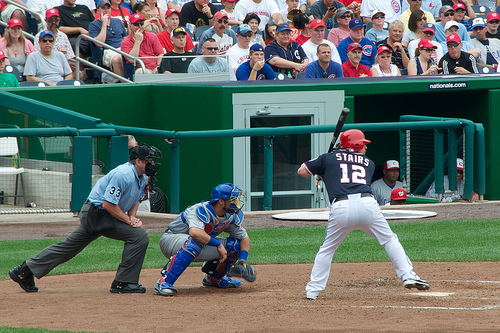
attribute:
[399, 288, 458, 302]
plate — home, white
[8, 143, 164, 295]
umpire — at game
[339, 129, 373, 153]
helmet — red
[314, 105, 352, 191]
bat — black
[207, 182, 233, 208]
helmet — blue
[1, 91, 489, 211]
railing — green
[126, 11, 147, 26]
hat — red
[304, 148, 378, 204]
jersey — blue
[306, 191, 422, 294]
pants — white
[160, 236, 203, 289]
knee pad — blue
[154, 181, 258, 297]
catcher — crouching, on team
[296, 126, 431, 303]
batter — about to hit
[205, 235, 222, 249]
wristband — blue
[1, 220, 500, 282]
grass — trimmed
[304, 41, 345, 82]
spectator — watching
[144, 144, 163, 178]
safety mask — black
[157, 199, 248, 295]
uniform — baseball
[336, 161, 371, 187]
number — twelve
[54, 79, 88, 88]
seat — empty